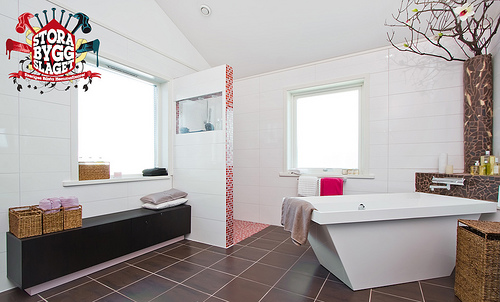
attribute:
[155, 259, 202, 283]
tile — brown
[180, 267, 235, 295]
tile — brown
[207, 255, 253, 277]
tile — brown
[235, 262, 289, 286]
tile — brown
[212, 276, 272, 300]
tile — brown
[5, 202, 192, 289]
shelf — long, black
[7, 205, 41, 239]
basket — wicker, square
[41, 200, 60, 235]
basket — wicker, square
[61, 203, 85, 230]
basket — wicker, square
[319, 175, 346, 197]
towel — hanging, pink, red, white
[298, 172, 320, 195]
towel — hanging, white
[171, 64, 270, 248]
shower — red, white, open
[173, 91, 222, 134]
window — square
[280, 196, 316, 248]
towel — brown, gray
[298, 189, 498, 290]
tub — white, standing, large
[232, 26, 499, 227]
wall — white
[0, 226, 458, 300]
floor — tile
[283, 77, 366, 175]
window — square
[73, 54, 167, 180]
window — square, large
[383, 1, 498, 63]
branches — brown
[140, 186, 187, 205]
cushion — gray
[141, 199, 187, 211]
cushion — white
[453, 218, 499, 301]
hamper — wicker, large, woven, wood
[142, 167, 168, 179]
towels — black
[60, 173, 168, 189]
window sill — large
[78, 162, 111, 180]
basket — wicker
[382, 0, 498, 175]
plant — brown